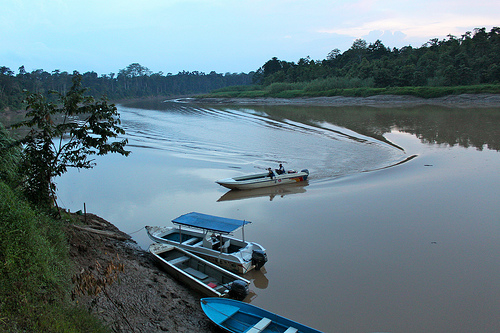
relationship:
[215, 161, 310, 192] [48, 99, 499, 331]
boat in water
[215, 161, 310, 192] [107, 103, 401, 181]
boat leaving wake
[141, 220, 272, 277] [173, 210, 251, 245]
boat has canopy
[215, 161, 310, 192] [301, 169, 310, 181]
boat has engine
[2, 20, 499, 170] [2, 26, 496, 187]
trees have leaves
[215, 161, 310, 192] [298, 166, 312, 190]
boat has engine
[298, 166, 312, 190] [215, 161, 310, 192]
engine on boat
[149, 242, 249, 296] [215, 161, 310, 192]
boat beside boat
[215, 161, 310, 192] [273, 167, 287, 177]
boat has seat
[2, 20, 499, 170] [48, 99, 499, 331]
trees are by water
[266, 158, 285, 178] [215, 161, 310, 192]
people in boat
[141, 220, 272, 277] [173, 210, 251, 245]
boat with canopy